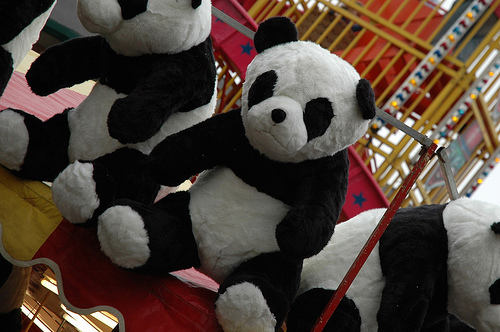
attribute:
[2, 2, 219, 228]
panda — stuffed, black, white, fluffy, ted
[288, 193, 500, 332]
panda — stuffed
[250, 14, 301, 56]
ear — black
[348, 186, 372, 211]
star — blue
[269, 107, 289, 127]
nose — black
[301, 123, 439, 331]
post — red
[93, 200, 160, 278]
foot — white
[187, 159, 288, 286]
belly — white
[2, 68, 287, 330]
table — red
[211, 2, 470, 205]
railing — gray